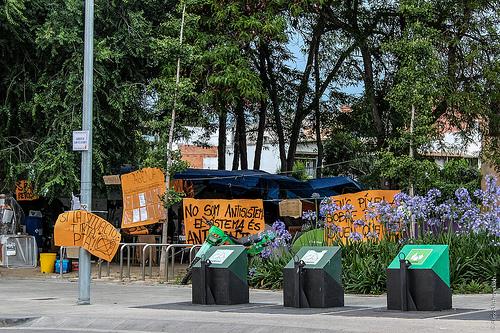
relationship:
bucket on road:
[178, 222, 269, 328] [53, 284, 484, 329]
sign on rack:
[183, 196, 267, 239] [125, 242, 160, 275]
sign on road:
[323, 189, 400, 245] [17, 272, 421, 330]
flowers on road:
[246, 173, 498, 285] [17, 272, 421, 330]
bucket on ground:
[36, 250, 60, 273] [2, 257, 499, 331]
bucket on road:
[36, 250, 60, 273] [31, 259, 231, 328]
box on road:
[373, 227, 454, 308] [34, 253, 472, 325]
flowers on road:
[246, 188, 499, 244] [34, 253, 472, 325]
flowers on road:
[246, 188, 499, 244] [74, 253, 461, 326]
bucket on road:
[193, 242, 256, 303] [53, 263, 456, 325]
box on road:
[276, 241, 347, 311] [53, 263, 456, 325]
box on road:
[390, 249, 454, 307] [53, 263, 456, 325]